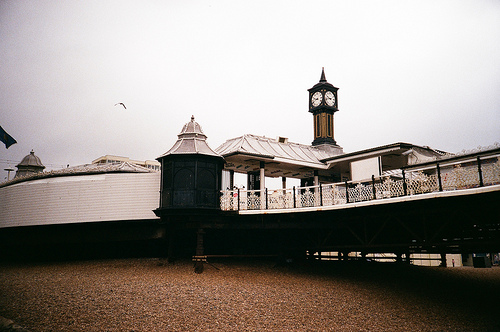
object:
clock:
[311, 91, 324, 107]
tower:
[308, 64, 339, 145]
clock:
[324, 91, 336, 107]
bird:
[114, 102, 127, 110]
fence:
[236, 155, 500, 211]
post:
[293, 186, 297, 208]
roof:
[212, 134, 333, 179]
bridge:
[239, 162, 500, 252]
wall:
[0, 171, 166, 225]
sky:
[0, 0, 500, 97]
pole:
[237, 189, 240, 210]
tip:
[320, 64, 326, 84]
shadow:
[461, 282, 498, 331]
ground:
[9, 265, 500, 331]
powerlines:
[0, 162, 17, 164]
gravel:
[249, 282, 253, 284]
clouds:
[431, 37, 476, 57]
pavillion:
[4, 148, 163, 256]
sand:
[360, 318, 382, 329]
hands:
[312, 99, 317, 104]